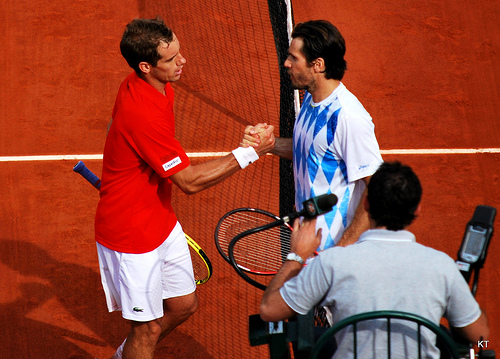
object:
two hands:
[239, 122, 276, 157]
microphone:
[287, 193, 338, 220]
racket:
[213, 207, 317, 277]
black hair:
[119, 15, 171, 77]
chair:
[248, 307, 494, 358]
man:
[259, 159, 487, 359]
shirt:
[279, 230, 481, 359]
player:
[238, 20, 385, 265]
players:
[93, 14, 386, 358]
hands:
[239, 122, 275, 156]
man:
[95, 14, 276, 357]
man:
[240, 19, 385, 253]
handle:
[72, 161, 103, 191]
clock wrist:
[282, 254, 306, 272]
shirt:
[93, 69, 189, 254]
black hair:
[292, 20, 347, 81]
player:
[92, 15, 276, 357]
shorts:
[97, 221, 197, 323]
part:
[228, 216, 291, 290]